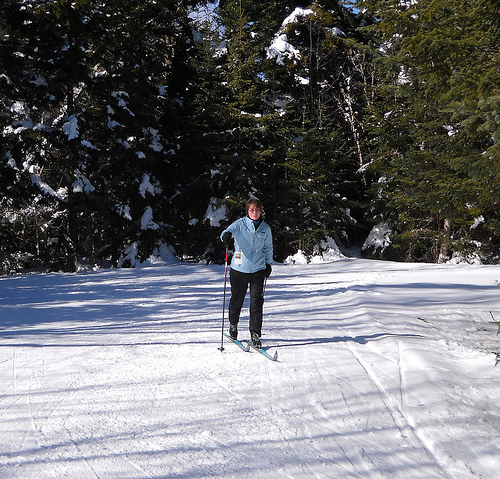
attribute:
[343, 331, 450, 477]
track — ski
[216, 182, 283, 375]
person — looking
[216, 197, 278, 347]
skier — posing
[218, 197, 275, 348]
woman — skiing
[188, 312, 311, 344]
her skis — narrow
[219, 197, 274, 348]
person — snow skiing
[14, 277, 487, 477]
trail — snow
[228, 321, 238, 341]
boot — nice, ski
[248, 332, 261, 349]
boot — nice, ski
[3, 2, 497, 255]
trees — pine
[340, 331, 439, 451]
tracks — ski, vehicle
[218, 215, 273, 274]
jacket — warm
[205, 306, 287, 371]
skier — woman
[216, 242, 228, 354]
pole — ski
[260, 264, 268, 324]
pole — ski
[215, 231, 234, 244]
glove — black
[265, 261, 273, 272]
glove — black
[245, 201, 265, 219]
hair — dark brown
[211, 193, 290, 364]
she — skiing